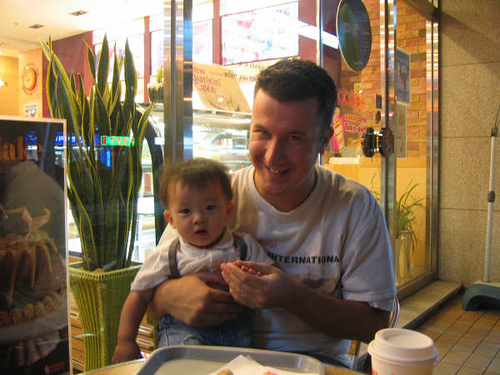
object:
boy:
[110, 156, 288, 365]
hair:
[160, 158, 229, 207]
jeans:
[153, 313, 261, 350]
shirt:
[128, 233, 271, 292]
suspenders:
[168, 237, 181, 277]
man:
[146, 48, 409, 374]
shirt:
[230, 164, 404, 365]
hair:
[249, 53, 339, 110]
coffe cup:
[362, 326, 441, 374]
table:
[71, 344, 372, 374]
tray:
[132, 343, 322, 374]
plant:
[37, 32, 158, 273]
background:
[0, 0, 249, 154]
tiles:
[462, 352, 495, 372]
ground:
[433, 312, 498, 373]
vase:
[65, 254, 144, 371]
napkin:
[229, 352, 267, 375]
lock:
[367, 126, 397, 154]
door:
[386, 0, 442, 294]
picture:
[21, 101, 40, 119]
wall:
[17, 54, 50, 118]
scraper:
[460, 122, 499, 313]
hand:
[219, 258, 287, 311]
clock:
[19, 67, 35, 91]